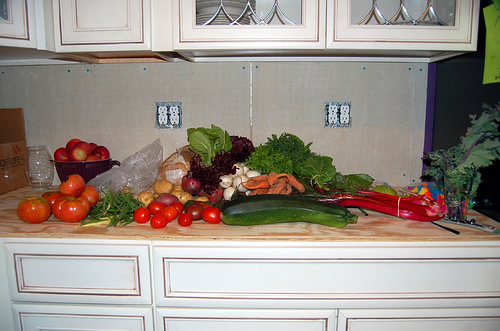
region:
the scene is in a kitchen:
[52, 4, 468, 329]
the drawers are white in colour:
[92, 236, 312, 328]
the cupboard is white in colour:
[49, 0, 348, 45]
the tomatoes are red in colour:
[28, 169, 97, 242]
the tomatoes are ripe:
[5, 159, 91, 242]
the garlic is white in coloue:
[211, 159, 244, 194]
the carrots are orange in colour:
[235, 165, 290, 195]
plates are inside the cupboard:
[197, 0, 277, 21]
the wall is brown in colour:
[225, 70, 280, 106]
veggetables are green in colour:
[250, 148, 338, 173]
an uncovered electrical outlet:
[322, 100, 354, 129]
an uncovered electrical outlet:
[154, 98, 184, 129]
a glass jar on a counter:
[22, 145, 55, 190]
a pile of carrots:
[236, 168, 306, 195]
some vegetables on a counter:
[14, 100, 499, 232]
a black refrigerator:
[431, 0, 498, 221]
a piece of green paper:
[481, 0, 498, 87]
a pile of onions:
[220, 159, 260, 199]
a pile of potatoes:
[119, 178, 209, 209]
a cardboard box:
[0, 106, 30, 193]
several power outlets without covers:
[140, 89, 364, 134]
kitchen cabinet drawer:
[0, 242, 160, 308]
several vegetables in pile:
[27, 123, 482, 245]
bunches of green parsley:
[264, 134, 327, 174]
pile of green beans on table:
[96, 188, 150, 224]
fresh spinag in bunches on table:
[179, 113, 232, 160]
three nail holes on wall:
[357, 63, 427, 73]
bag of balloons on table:
[396, 177, 448, 200]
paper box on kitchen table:
[0, 100, 32, 202]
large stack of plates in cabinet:
[196, 0, 252, 22]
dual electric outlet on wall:
[317, 100, 357, 127]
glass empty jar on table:
[17, 136, 62, 188]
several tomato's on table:
[141, 199, 190, 233]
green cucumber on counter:
[217, 189, 362, 230]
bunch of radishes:
[331, 182, 448, 230]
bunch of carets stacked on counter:
[242, 163, 304, 203]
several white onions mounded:
[211, 160, 258, 197]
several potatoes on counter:
[139, 177, 187, 204]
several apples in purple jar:
[46, 133, 114, 184]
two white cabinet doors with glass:
[177, 0, 482, 63]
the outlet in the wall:
[327, 103, 338, 114]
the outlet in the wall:
[340, 104, 348, 114]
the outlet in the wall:
[327, 113, 336, 123]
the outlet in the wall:
[340, 111, 350, 123]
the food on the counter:
[16, 105, 497, 227]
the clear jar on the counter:
[22, 144, 53, 189]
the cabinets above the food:
[0, 0, 480, 67]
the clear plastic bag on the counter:
[85, 138, 162, 197]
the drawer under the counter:
[2, 242, 151, 304]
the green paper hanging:
[479, 3, 499, 83]